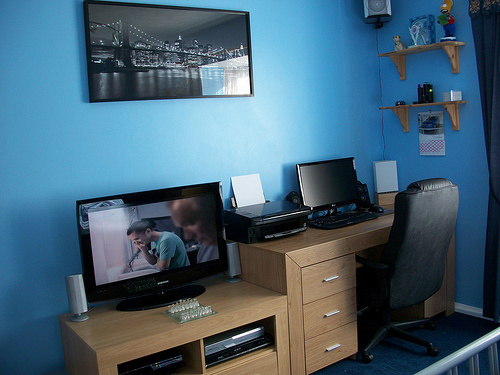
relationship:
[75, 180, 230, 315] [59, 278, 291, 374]
tv on table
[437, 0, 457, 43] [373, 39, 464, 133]
figurine on shelves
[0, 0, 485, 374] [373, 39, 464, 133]
walls have shelves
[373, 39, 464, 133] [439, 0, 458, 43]
shelves have figurine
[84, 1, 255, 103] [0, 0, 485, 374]
photograph on walls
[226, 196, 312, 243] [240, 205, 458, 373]
printer on desk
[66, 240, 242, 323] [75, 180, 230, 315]
speakers next to tv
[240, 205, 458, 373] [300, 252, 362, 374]
desk has drawers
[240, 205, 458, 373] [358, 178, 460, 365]
desk has chair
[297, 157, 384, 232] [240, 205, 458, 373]
cpu on desk